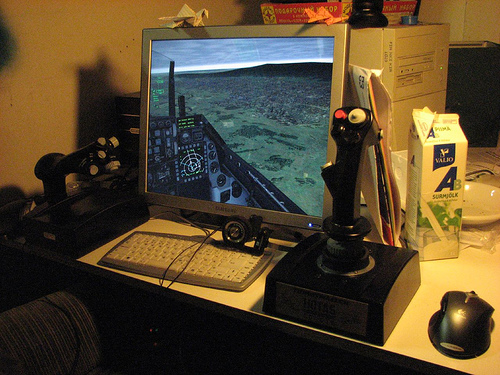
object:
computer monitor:
[137, 22, 349, 241]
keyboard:
[97, 231, 274, 291]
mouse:
[428, 290, 494, 359]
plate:
[461, 181, 500, 225]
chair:
[0, 292, 111, 375]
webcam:
[222, 218, 249, 247]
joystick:
[34, 136, 121, 198]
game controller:
[319, 105, 383, 270]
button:
[335, 109, 347, 119]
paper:
[349, 64, 401, 247]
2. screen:
[145, 37, 334, 217]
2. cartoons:
[147, 35, 335, 218]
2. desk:
[75, 147, 499, 375]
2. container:
[403, 105, 467, 260]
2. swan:
[158, 3, 208, 29]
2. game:
[146, 36, 332, 219]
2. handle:
[320, 106, 380, 273]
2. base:
[262, 232, 421, 346]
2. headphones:
[222, 214, 270, 256]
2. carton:
[400, 105, 468, 261]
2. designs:
[157, 2, 347, 30]